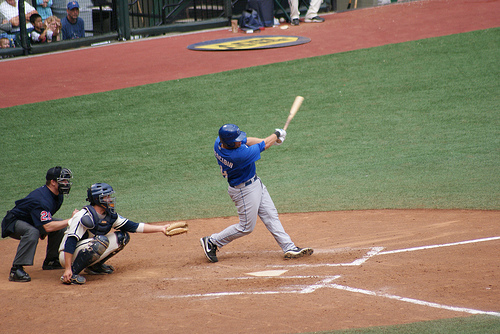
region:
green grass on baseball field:
[0, 25, 497, 225]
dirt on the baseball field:
[2, 206, 497, 332]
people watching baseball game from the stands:
[0, 0, 86, 47]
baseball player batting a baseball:
[200, 93, 315, 262]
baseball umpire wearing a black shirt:
[0, 165, 77, 282]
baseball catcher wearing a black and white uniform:
[57, 182, 188, 285]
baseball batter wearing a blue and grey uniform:
[199, 123, 314, 262]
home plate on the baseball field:
[246, 267, 288, 276]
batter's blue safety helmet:
[218, 122, 245, 142]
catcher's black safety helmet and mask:
[86, 180, 113, 208]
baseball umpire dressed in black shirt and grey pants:
[3, 163, 79, 280]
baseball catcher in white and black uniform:
[56, 180, 190, 285]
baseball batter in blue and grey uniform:
[198, 123, 313, 264]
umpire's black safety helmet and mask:
[45, 165, 70, 194]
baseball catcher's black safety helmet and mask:
[86, 183, 116, 211]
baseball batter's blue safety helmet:
[217, 123, 248, 144]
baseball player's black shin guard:
[67, 235, 107, 275]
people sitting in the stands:
[0, 0, 87, 51]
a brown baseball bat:
[282, 89, 307, 129]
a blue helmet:
[215, 119, 250, 146]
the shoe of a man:
[285, 243, 312, 257]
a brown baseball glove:
[165, 221, 191, 235]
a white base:
[243, 260, 290, 280]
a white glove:
[270, 122, 285, 137]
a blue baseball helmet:
[85, 180, 115, 205]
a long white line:
[153, 265, 344, 286]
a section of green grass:
[2, 27, 498, 225]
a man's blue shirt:
[211, 130, 263, 188]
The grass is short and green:
[353, 60, 476, 189]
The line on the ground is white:
[343, 280, 468, 322]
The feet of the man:
[196, 232, 317, 265]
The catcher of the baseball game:
[56, 178, 191, 291]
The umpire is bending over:
[0, 153, 78, 285]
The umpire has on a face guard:
[43, 164, 78, 196]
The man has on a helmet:
[213, 115, 250, 150]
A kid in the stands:
[29, 9, 64, 50]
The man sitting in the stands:
[58, 2, 92, 44]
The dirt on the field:
[73, 288, 228, 332]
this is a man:
[178, 52, 348, 302]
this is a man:
[50, 175, 195, 302]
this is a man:
[0, 157, 80, 285]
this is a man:
[65, 3, 87, 46]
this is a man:
[27, 6, 64, 53]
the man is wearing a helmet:
[198, 109, 253, 154]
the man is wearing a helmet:
[75, 165, 126, 213]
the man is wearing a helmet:
[22, 149, 84, 199]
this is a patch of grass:
[325, 110, 395, 172]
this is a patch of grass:
[128, 106, 182, 187]